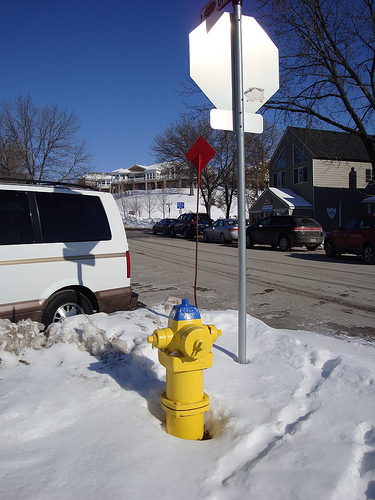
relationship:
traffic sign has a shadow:
[189, 3, 282, 131] [218, 343, 237, 361]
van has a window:
[1, 179, 138, 323] [34, 197, 111, 244]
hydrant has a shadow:
[146, 299, 222, 441] [95, 347, 167, 417]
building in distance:
[265, 127, 374, 228] [2, 0, 372, 235]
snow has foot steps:
[3, 300, 373, 499] [320, 348, 342, 378]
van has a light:
[1, 179, 138, 323] [126, 253, 132, 279]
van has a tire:
[1, 179, 138, 323] [38, 288, 98, 334]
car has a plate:
[249, 214, 321, 250] [310, 237, 318, 248]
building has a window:
[265, 127, 374, 228] [347, 169, 357, 194]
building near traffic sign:
[265, 127, 374, 228] [189, 3, 282, 131]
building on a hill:
[78, 161, 264, 191] [117, 188, 259, 232]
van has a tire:
[1, 179, 138, 323] [46, 288, 93, 324]